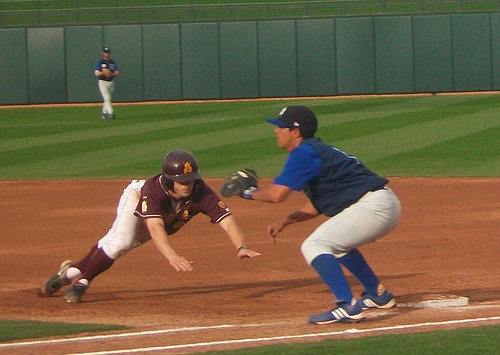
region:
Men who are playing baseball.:
[68, 43, 368, 345]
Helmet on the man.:
[126, 115, 206, 207]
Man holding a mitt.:
[103, 120, 386, 247]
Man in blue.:
[221, 84, 442, 339]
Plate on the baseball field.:
[396, 280, 498, 327]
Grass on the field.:
[136, 89, 280, 194]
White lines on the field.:
[76, 236, 268, 351]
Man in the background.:
[78, 50, 155, 129]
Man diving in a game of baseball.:
[46, 141, 296, 326]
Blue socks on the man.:
[266, 233, 413, 325]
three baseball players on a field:
[24, 43, 422, 353]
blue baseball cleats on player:
[299, 290, 406, 337]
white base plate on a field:
[396, 286, 471, 323]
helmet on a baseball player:
[161, 141, 206, 183]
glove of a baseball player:
[215, 167, 259, 204]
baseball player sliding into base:
[38, 143, 250, 310]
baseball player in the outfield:
[85, 42, 131, 117]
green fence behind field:
[191, 26, 478, 82]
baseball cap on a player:
[264, 102, 324, 136]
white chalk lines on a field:
[91, 313, 308, 347]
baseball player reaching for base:
[28, 146, 476, 330]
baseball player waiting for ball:
[214, 86, 418, 329]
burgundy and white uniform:
[102, 150, 213, 300]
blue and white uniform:
[262, 106, 423, 298]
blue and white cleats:
[296, 289, 413, 324]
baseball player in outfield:
[70, 35, 173, 140]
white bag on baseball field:
[385, 281, 480, 327]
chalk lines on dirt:
[115, 307, 495, 354]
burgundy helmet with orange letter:
[150, 139, 211, 202]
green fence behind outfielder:
[44, 16, 379, 133]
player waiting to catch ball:
[220, 102, 403, 323]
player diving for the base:
[42, 147, 260, 301]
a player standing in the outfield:
[95, 47, 117, 119]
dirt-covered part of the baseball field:
[1, 179, 497, 354]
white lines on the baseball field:
[1, 297, 498, 353]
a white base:
[399, 292, 468, 309]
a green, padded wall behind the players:
[1, 9, 498, 105]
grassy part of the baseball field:
[1, 92, 499, 180]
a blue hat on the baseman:
[263, 105, 317, 132]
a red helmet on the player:
[160, 150, 200, 195]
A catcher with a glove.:
[218, 104, 403, 326]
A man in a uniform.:
[41, 150, 263, 305]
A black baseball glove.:
[218, 165, 260, 201]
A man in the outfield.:
[91, 45, 121, 120]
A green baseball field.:
[1, 89, 499, 350]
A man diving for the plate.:
[38, 147, 264, 302]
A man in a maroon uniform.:
[38, 147, 263, 305]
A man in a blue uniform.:
[218, 103, 403, 325]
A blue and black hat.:
[266, 105, 318, 139]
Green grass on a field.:
[0, 93, 498, 179]